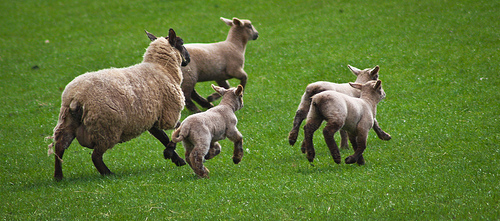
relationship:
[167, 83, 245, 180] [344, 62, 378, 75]
animal has ears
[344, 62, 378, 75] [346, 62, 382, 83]
ears on head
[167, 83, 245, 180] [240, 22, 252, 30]
animal has eye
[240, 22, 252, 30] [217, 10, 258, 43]
eye on head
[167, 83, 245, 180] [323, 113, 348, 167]
animal has leg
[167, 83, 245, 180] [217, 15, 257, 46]
animal has head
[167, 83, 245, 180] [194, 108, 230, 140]
animal has torso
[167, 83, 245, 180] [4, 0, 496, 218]
animal on grass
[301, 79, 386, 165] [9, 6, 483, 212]
animal in field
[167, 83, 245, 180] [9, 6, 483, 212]
animal in field